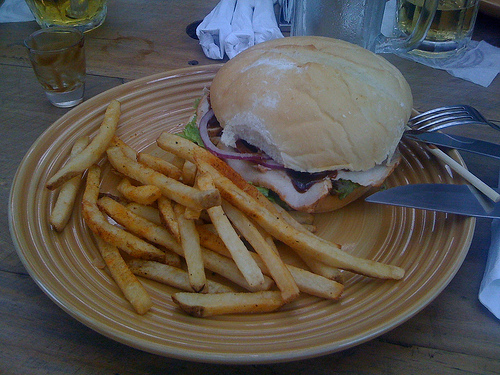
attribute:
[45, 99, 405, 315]
french fries — golden, seasoned, piled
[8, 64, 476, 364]
plate — tan, brown, porcelain, light brown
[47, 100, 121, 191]
french fry — golden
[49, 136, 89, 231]
french fry — golden, yellow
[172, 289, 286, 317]
french fry — golden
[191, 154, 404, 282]
french fry — golden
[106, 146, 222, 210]
french fry — golden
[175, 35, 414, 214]
sandwich — uneaten, whole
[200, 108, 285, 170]
onion — purple, ring, red onion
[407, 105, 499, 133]
fork — metal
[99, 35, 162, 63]
stain — water ring, moisture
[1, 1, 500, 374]
table — wooden, brown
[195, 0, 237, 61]
napkin — rolled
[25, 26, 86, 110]
glass — small, small shot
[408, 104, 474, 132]
tines — metal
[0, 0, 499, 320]
napkins — white